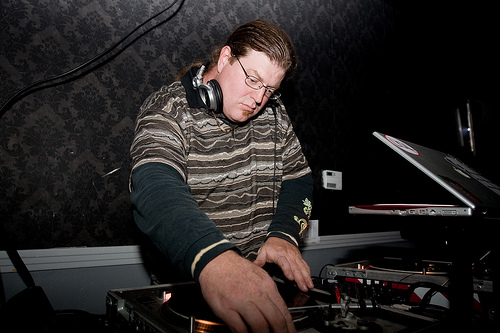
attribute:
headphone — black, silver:
[176, 53, 224, 121]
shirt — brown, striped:
[124, 76, 319, 289]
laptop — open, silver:
[341, 123, 484, 227]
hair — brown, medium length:
[164, 15, 300, 86]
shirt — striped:
[124, 76, 320, 266]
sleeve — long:
[123, 157, 245, 290]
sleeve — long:
[258, 166, 325, 253]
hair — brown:
[166, 16, 298, 79]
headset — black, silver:
[178, 52, 228, 117]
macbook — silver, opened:
[342, 125, 484, 227]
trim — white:
[29, 237, 179, 276]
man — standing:
[123, 16, 336, 326]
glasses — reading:
[232, 54, 286, 103]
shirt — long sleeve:
[128, 74, 328, 273]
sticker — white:
[364, 128, 429, 158]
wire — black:
[20, 19, 207, 115]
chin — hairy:
[229, 101, 264, 127]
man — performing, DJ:
[115, 28, 371, 330]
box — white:
[295, 160, 367, 200]